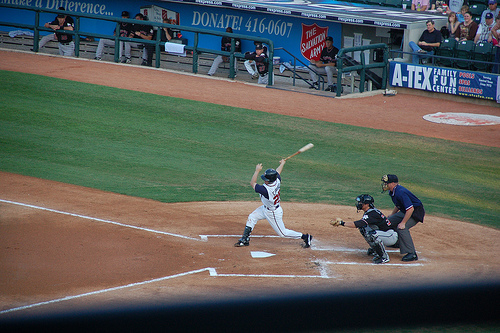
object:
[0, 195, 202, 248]
base line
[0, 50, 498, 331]
field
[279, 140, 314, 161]
bat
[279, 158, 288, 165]
hand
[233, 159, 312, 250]
player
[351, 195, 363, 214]
mask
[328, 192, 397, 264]
catcher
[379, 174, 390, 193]
mask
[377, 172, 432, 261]
umpire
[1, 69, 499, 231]
grass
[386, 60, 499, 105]
advertisement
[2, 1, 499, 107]
stands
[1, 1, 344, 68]
advertisement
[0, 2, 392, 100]
dugout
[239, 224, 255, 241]
shin protector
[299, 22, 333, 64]
logo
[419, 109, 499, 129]
batter's circle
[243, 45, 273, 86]
players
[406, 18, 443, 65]
spectators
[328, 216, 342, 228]
mitt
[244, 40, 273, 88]
man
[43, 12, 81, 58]
man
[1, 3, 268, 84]
fence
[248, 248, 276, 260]
home plate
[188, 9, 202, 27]
lettering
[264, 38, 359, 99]
staircase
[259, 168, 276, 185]
helmet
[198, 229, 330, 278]
batter's box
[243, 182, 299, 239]
uniform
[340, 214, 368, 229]
arm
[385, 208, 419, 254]
pants